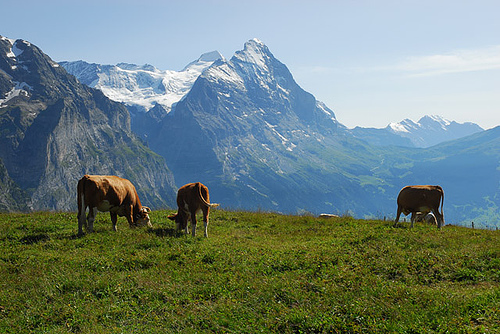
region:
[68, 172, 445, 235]
the cows on top of the hill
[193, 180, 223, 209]
the wagging tail of the cow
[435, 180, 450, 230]
the cows tail hanging down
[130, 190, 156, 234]
the cows face grazing in the grass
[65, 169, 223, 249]
the cattle eating of the ground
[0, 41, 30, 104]
the snow on the mountain valley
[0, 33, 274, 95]
the snowy mountain tops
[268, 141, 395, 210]
the green trees in the valley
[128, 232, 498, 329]
the grass field on top of the hill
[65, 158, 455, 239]
the cattle on the hilltop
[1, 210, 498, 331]
A grassy hill near a mountain chain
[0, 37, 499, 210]
A large mountain chain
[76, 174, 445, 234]
Three cows grazing on a hill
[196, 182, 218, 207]
A cow's wagging tail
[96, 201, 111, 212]
A cow's utter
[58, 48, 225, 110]
A snow cap on a mountain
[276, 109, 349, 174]
Rugged grass growing on the side of a mountain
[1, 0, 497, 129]
A blue, lightly clouded sky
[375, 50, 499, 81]
A small, flat cloud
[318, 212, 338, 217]
A large stone in a field of grass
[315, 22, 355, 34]
this is the sky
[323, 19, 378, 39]
the sky is blue in color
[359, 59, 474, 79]
the sky has clouds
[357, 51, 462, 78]
the clouds are white in color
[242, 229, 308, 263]
this is the grass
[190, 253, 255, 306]
the grass is green in color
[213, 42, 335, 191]
this is a mountain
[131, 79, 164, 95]
the peak has snow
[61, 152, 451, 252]
these are some cows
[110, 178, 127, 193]
the fur is brown in color